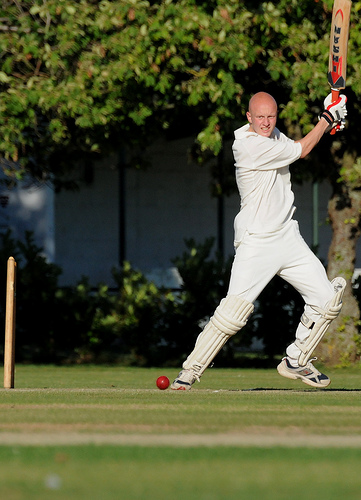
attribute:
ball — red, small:
[156, 376, 171, 391]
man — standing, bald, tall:
[170, 91, 347, 391]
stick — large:
[327, 1, 354, 136]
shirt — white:
[233, 122, 302, 245]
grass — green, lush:
[0, 363, 360, 499]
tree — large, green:
[0, 1, 360, 368]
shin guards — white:
[182, 276, 347, 375]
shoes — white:
[168, 357, 332, 391]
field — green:
[0, 1, 360, 499]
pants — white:
[182, 219, 337, 372]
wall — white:
[0, 132, 359, 357]